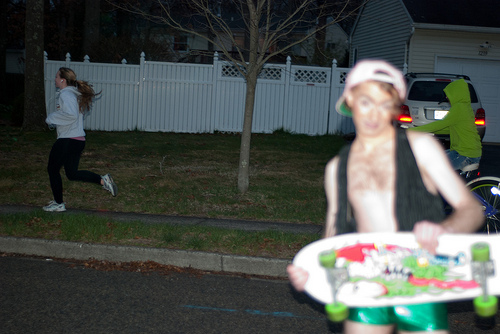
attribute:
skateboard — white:
[278, 219, 499, 318]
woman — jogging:
[29, 57, 127, 218]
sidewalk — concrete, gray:
[0, 196, 329, 236]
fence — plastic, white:
[85, 48, 339, 134]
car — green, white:
[405, 65, 492, 140]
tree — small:
[121, 4, 319, 197]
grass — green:
[116, 130, 320, 209]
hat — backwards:
[328, 55, 413, 116]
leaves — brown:
[77, 256, 215, 276]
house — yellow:
[346, 1, 500, 76]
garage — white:
[429, 55, 499, 86]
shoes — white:
[35, 169, 118, 217]